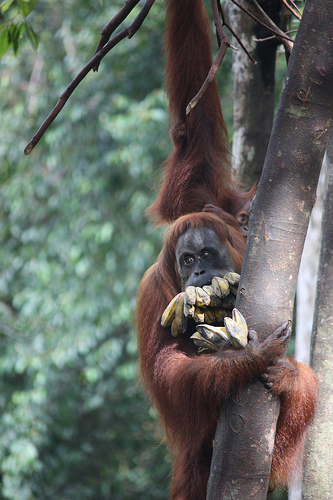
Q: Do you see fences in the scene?
A: No, there are no fences.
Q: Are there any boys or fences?
A: No, there are no fences or boys.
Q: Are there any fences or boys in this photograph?
A: No, there are no fences or boys.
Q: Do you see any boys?
A: No, there are no boys.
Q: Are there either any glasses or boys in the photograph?
A: No, there are no boys or glasses.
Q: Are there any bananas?
A: Yes, there are bananas.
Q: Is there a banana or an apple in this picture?
A: Yes, there are bananas.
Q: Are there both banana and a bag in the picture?
A: No, there are bananas but no bags.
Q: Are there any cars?
A: No, there are no cars.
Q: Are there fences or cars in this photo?
A: No, there are no cars or fences.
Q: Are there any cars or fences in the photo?
A: No, there are no cars or fences.